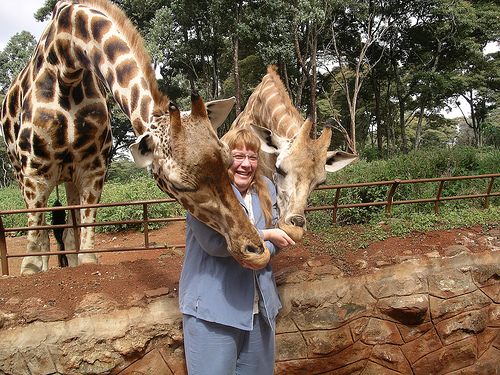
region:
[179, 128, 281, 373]
woman in a blue suit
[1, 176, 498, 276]
long wooden fence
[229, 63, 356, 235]
light colored giraffe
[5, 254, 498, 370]
brown wall of man made rocks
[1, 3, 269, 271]
giraffe with black spots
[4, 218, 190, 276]
dirt behind the giraffe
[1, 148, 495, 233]
short green bushes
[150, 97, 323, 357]
woman is feeding the giraffes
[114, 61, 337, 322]
the giraffe is brown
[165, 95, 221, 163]
horns on the giraffe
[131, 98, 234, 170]
ears on the giraffe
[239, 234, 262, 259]
the nostril is flared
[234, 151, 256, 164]
woman is wearing glasses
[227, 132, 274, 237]
the hair is long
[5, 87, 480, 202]
vegetation behind the giraffe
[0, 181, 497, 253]
the rail is iron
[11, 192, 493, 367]
the rail is on the wall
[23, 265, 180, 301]
the dirt is brown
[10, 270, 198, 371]
dirt on the wall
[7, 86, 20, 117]
brown spot on giraffe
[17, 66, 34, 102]
brown spot on giraffe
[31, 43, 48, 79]
brown spot on giraffe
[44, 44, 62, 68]
brown spot on giraffe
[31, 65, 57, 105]
brown spot on giraffe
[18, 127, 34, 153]
brown spot on giraffe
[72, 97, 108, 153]
brown spot on giraffe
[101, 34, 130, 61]
brown spot on giraffe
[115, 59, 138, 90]
brown spot on giraffe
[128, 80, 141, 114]
brown spot on giraffe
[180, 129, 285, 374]
woman standing in front of a wall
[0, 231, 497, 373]
stone wall behind woman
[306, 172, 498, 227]
metal railing on top of wall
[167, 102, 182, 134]
horn on giraffe's head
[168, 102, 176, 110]
tip of horn is black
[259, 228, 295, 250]
hand under giraffe head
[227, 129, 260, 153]
woman has bangs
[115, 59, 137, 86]
spot visible on giraffe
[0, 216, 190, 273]
dirt path visible behind railing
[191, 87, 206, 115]
horn to the right of horn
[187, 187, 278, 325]
the jacket is blue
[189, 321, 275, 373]
the pants are blue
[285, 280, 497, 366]
the wall is stone